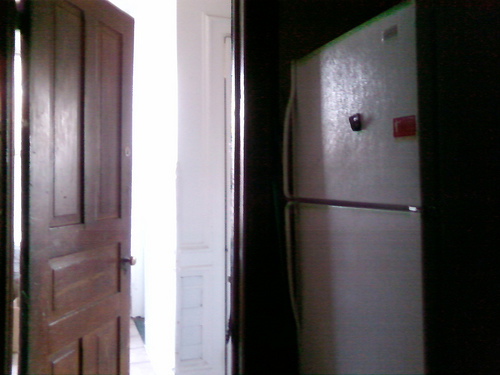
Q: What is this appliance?
A: Refridgerator.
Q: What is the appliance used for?
A: Cooling food.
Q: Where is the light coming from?
A: The door.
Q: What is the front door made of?
A: Wood.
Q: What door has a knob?
A: The wood door.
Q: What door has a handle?
A: Fridge door.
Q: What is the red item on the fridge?
A: A magnet.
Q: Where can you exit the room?
A: Through the wooden door.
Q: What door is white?
A: The appliance door.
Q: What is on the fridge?
A: A shadow.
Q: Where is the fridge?
A: In a dark room.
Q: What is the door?
A: Brown wood.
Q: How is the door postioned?
A: Open.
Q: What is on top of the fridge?
A: A green line.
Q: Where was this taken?
A: In the kitchen.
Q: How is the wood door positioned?
A: Ajar.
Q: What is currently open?
A: The door.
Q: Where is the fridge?
A: By open door.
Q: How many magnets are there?
A: 2.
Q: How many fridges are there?
A: 1.